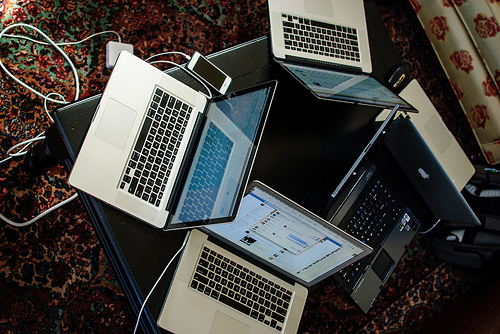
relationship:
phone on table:
[182, 42, 236, 94] [52, 17, 484, 329]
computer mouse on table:
[386, 64, 409, 90] [52, 17, 484, 329]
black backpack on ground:
[442, 161, 499, 306] [2, 238, 100, 328]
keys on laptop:
[130, 85, 192, 211] [73, 52, 282, 237]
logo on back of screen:
[418, 165, 430, 180] [371, 114, 480, 230]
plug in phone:
[158, 32, 188, 76] [188, 26, 256, 122]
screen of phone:
[181, 97, 251, 206] [180, 47, 235, 97]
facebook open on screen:
[241, 200, 350, 277] [214, 180, 372, 283]